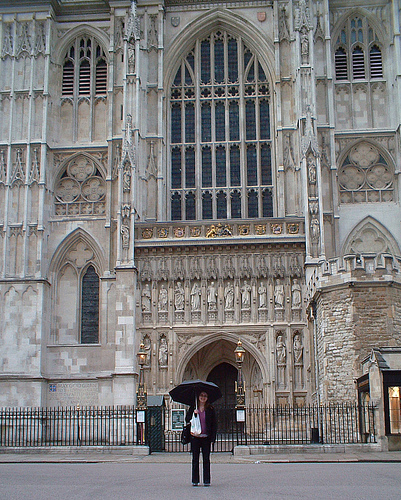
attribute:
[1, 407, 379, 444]
fence — black, short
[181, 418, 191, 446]
bag — black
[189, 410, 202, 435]
bag — white, plastic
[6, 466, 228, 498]
road — paved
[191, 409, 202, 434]
plastic bag — used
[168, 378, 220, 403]
umbrella — black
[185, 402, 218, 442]
jacket — black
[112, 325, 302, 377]
lights — on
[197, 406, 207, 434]
shirt — purple, v-neck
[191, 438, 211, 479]
pants — black